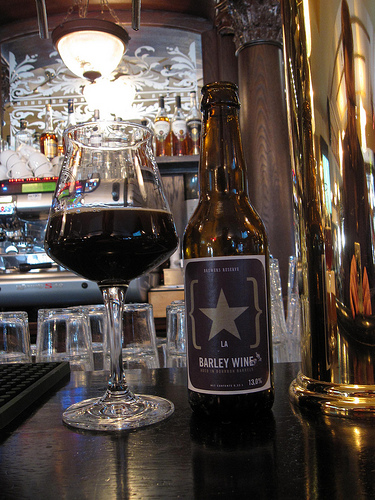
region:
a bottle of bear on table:
[112, 102, 356, 392]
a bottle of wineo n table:
[127, 151, 357, 434]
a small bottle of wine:
[148, 239, 329, 496]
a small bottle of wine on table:
[156, 284, 309, 496]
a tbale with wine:
[167, 300, 286, 495]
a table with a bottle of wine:
[170, 283, 313, 498]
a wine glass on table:
[48, 194, 281, 471]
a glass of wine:
[50, 164, 238, 439]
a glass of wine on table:
[33, 164, 255, 496]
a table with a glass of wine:
[22, 162, 235, 495]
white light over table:
[54, 22, 138, 89]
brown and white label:
[171, 262, 269, 402]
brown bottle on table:
[165, 91, 286, 441]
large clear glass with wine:
[62, 120, 168, 436]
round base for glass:
[67, 386, 165, 434]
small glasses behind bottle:
[9, 301, 196, 370]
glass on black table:
[37, 361, 282, 488]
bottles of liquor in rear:
[19, 98, 204, 168]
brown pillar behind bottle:
[229, 39, 289, 247]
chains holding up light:
[35, 0, 126, 42]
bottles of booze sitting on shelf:
[146, 101, 202, 162]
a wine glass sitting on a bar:
[57, 137, 197, 416]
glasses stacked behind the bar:
[55, 304, 183, 361]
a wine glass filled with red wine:
[53, 153, 164, 426]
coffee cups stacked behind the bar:
[6, 146, 74, 175]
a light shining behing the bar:
[34, 23, 159, 101]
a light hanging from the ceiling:
[50, 17, 124, 87]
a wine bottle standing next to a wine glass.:
[67, 123, 268, 441]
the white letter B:
[195, 352, 207, 372]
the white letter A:
[201, 352, 210, 371]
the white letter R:
[204, 355, 214, 372]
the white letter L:
[210, 352, 219, 369]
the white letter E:
[215, 352, 228, 372]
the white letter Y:
[220, 355, 231, 369]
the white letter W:
[227, 353, 242, 368]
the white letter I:
[235, 355, 248, 370]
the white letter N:
[239, 352, 251, 369]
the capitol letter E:
[245, 352, 258, 370]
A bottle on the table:
[177, 76, 283, 425]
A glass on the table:
[44, 109, 181, 435]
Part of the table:
[200, 448, 241, 474]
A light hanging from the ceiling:
[42, 1, 133, 86]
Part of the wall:
[222, 53, 237, 73]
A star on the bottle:
[196, 285, 250, 343]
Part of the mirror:
[150, 33, 164, 37]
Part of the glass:
[51, 323, 76, 343]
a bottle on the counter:
[188, 265, 290, 416]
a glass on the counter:
[106, 290, 157, 396]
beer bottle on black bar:
[170, 74, 283, 432]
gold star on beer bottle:
[184, 247, 281, 405]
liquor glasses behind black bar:
[29, 283, 200, 399]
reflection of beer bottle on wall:
[162, 66, 345, 374]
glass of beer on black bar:
[41, 117, 180, 444]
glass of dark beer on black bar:
[45, 115, 177, 425]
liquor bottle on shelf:
[150, 77, 201, 158]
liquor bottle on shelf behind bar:
[11, 87, 208, 365]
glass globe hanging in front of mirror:
[47, 3, 137, 85]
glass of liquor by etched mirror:
[37, 93, 58, 163]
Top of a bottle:
[197, 80, 242, 145]